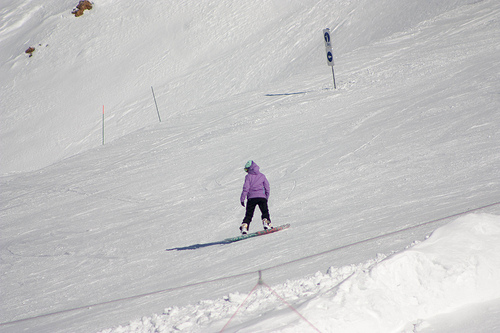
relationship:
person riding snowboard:
[230, 158, 272, 234] [199, 221, 292, 243]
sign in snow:
[321, 28, 338, 65] [117, 84, 494, 323]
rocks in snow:
[19, 40, 54, 62] [117, 84, 494, 323]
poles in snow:
[90, 86, 168, 143] [117, 84, 494, 323]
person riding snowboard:
[236, 158, 273, 237] [199, 221, 292, 243]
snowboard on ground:
[199, 221, 292, 243] [43, 205, 497, 328]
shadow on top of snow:
[166, 236, 228, 255] [117, 84, 494, 323]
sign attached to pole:
[321, 28, 338, 65] [329, 69, 340, 89]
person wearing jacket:
[236, 158, 273, 237] [244, 174, 275, 202]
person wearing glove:
[236, 158, 273, 237] [241, 200, 246, 210]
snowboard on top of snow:
[199, 221, 292, 243] [117, 84, 494, 323]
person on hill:
[230, 158, 272, 234] [117, 64, 496, 232]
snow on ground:
[117, 84, 494, 323] [43, 205, 497, 328]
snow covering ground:
[117, 84, 494, 323] [43, 205, 497, 328]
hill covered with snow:
[117, 64, 496, 232] [117, 84, 494, 323]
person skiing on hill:
[230, 158, 272, 234] [117, 64, 496, 232]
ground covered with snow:
[43, 205, 497, 328] [117, 84, 494, 323]